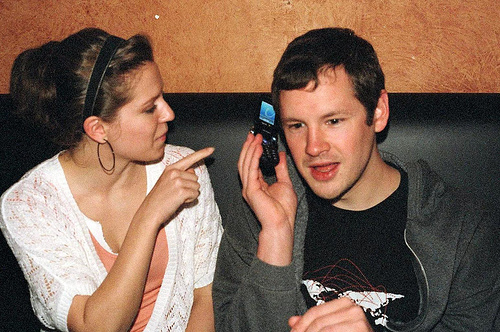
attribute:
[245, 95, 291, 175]
phone — black, cellular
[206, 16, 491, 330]
man — talking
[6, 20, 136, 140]
hair — brown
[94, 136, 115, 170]
earring — hanging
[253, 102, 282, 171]
cellphone —  Man's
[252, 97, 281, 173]
cellphone —  Black,  flip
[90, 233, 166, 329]
shirt —  Peach,   woman's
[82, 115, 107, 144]
ear —   woman's, the right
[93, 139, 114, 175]
earring —  Hoop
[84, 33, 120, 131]
headband —  Black,  woman's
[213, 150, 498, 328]
jacket —  Grey,  man's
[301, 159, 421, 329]
shirt —  Black, tee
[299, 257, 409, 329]
design —  red and white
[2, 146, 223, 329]
cardigan —  white,  Short sleeved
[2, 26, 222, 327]
woman — pointing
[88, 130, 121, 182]
earring — large, hoop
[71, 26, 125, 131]
headband — black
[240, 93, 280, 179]
phone — black, small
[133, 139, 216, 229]
hand — pointing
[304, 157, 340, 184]
mouth — open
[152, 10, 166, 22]
spot — white